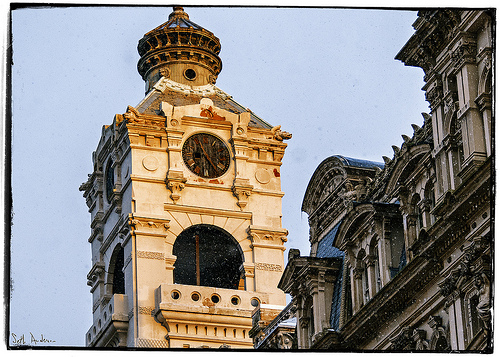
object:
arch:
[103, 243, 127, 292]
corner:
[123, 174, 145, 187]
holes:
[248, 297, 261, 307]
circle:
[255, 169, 272, 184]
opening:
[170, 289, 180, 300]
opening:
[192, 291, 198, 300]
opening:
[212, 295, 219, 305]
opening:
[229, 295, 241, 305]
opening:
[250, 297, 260, 307]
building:
[76, 7, 294, 348]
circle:
[140, 155, 158, 172]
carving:
[163, 164, 188, 203]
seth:
[9, 331, 29, 347]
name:
[4, 331, 101, 349]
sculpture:
[476, 277, 494, 343]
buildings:
[247, 9, 493, 353]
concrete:
[144, 184, 156, 207]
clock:
[180, 132, 233, 179]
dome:
[135, 7, 223, 95]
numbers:
[185, 157, 195, 169]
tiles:
[330, 251, 337, 257]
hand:
[201, 152, 220, 172]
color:
[320, 240, 330, 255]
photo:
[5, 5, 494, 352]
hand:
[196, 136, 206, 153]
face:
[182, 130, 229, 178]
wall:
[131, 63, 289, 349]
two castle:
[78, 7, 496, 356]